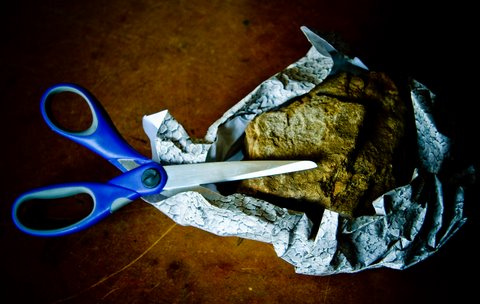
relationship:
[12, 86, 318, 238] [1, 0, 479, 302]
scissors on table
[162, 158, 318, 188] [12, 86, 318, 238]
blades of scissors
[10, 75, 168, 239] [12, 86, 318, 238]
blue handles on scissors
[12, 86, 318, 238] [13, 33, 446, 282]
scissors on table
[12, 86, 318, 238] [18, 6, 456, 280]
scissors on table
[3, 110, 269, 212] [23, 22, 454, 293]
scissors on table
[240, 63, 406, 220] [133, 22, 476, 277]
brown rock in paper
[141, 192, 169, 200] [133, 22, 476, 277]
blade hidden by paper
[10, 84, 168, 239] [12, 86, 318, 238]
blue handles of scissors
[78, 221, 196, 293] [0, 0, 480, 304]
scratch on floor